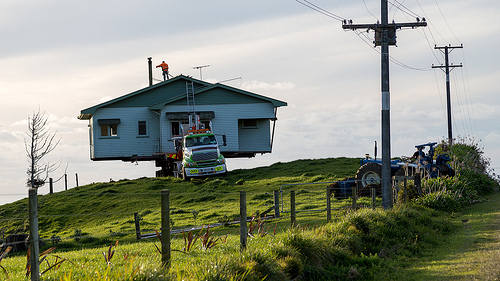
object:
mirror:
[222, 134, 227, 147]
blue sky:
[166, 0, 231, 26]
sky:
[73, 18, 130, 66]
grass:
[74, 190, 131, 225]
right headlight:
[216, 159, 224, 163]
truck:
[155, 129, 228, 180]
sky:
[264, 32, 361, 94]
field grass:
[1, 157, 498, 279]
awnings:
[166, 111, 216, 120]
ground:
[463, 230, 495, 247]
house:
[76, 57, 287, 162]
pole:
[28, 188, 38, 281]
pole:
[160, 189, 171, 267]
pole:
[239, 190, 247, 248]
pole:
[291, 190, 296, 225]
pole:
[327, 186, 332, 223]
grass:
[280, 236, 344, 264]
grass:
[170, 221, 220, 251]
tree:
[24, 108, 69, 194]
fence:
[27, 188, 377, 281]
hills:
[18, 157, 418, 249]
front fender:
[185, 164, 226, 177]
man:
[156, 61, 169, 81]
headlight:
[186, 162, 193, 166]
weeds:
[346, 257, 406, 279]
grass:
[215, 252, 255, 273]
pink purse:
[248, 213, 278, 238]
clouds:
[308, 86, 378, 131]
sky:
[1, 55, 66, 105]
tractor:
[330, 141, 455, 201]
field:
[0, 158, 499, 281]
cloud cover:
[294, 26, 328, 66]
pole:
[341, 0, 426, 211]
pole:
[431, 43, 464, 145]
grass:
[356, 216, 410, 254]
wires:
[396, 5, 451, 19]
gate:
[280, 179, 397, 214]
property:
[2, 155, 483, 275]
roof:
[78, 74, 288, 120]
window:
[186, 135, 217, 147]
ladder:
[186, 81, 196, 115]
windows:
[101, 124, 117, 137]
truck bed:
[155, 158, 181, 177]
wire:
[316, 4, 342, 21]